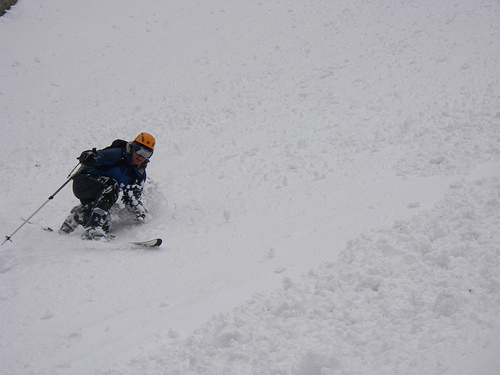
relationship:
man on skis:
[66, 121, 171, 199] [58, 222, 219, 275]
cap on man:
[135, 132, 156, 150] [60, 132, 157, 243]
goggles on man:
[127, 145, 157, 159] [60, 132, 157, 243]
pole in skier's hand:
[2, 164, 87, 243] [76, 144, 122, 182]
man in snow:
[60, 132, 157, 243] [0, 0, 500, 375]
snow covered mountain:
[262, 67, 414, 178] [310, 42, 491, 160]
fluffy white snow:
[295, 55, 363, 101] [262, 67, 414, 178]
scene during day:
[87, 35, 464, 270] [48, 13, 436, 176]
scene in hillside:
[87, 35, 464, 270] [219, 25, 392, 138]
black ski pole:
[18, 167, 84, 238] [35, 144, 126, 217]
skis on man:
[58, 222, 219, 275] [66, 121, 171, 199]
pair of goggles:
[116, 139, 183, 160] [127, 145, 157, 159]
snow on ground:
[262, 67, 414, 178] [317, 79, 438, 144]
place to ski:
[215, 50, 367, 165] [257, 45, 381, 148]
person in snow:
[66, 121, 171, 199] [262, 67, 414, 178]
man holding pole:
[60, 132, 157, 243] [2, 164, 87, 243]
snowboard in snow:
[18, 167, 84, 238] [262, 67, 414, 178]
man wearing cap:
[60, 132, 157, 243] [140, 136, 147, 146]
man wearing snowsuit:
[60, 132, 157, 243] [67, 160, 171, 213]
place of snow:
[215, 50, 367, 165] [262, 67, 414, 178]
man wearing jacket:
[60, 132, 157, 243] [76, 144, 122, 182]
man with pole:
[60, 132, 157, 243] [2, 164, 87, 243]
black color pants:
[18, 167, 84, 238] [89, 172, 118, 211]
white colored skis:
[107, 230, 215, 291] [131, 238, 163, 248]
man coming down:
[60, 132, 157, 243] [146, 91, 442, 219]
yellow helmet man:
[130, 112, 159, 150] [60, 132, 157, 243]